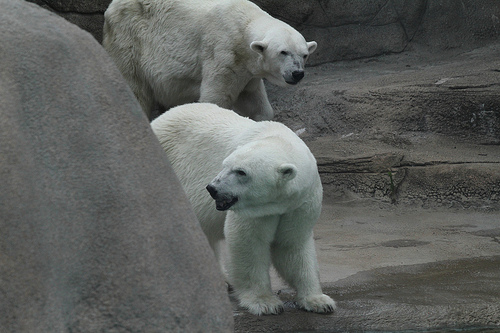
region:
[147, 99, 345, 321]
Polar bear in the forefront.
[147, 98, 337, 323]
White fur on the bear.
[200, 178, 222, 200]
black nose on the bear.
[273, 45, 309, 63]
black eyes on the bear.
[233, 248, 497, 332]
Water in the forefront.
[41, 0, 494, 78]
Rock wall in the background.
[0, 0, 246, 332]
large rock in the forefront.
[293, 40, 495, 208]
Rock ledges in the background.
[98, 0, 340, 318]
Two bears in the enclosure.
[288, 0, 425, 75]
Crevices in the rock.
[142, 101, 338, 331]
polar bear looking around the corner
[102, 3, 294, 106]
polar bear following behind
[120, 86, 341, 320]
polar bear next to a large rock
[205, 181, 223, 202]
polar bear's black nose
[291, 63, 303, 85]
black nose on polar bear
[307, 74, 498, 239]
steps in stone next to polar bear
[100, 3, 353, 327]
pair of polar bears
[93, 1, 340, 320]
two polar bears on all fours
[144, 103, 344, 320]
polar bear with gleaming white fur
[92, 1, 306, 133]
polar bear is dirty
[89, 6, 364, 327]
two polar bears at the zoo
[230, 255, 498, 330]
the water on the ground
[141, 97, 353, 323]
the polar bear is white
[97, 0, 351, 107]
the polar bear is white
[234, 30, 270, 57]
the ear of the polar bear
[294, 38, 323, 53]
the ear of the polar bear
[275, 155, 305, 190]
the ear of the polar bear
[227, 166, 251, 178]
the eye of the polar bear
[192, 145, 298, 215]
the head of the polar bear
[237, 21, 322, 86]
the head of the polar bear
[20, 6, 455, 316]
The bears are walking together slowly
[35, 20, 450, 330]
The bears are looking for food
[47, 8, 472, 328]
The bears have very sharp teeth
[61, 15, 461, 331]
The bears are very big and strong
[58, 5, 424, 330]
The bears have white color fur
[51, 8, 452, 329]
The bears can smell very good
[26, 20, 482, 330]
The bears have big powerful paws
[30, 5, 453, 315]
The bears are fierce and unpredictable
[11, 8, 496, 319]
The bears are held in captivity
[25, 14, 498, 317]
The bears are in a local zoo